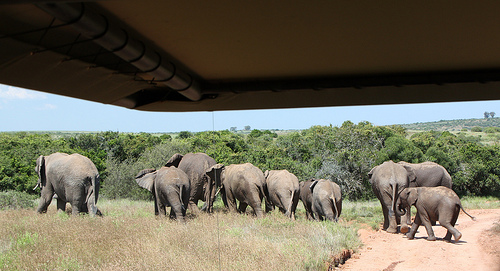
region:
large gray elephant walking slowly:
[19, 135, 101, 218]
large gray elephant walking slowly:
[140, 165, 197, 222]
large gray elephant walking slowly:
[166, 148, 210, 171]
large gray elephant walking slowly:
[207, 153, 264, 214]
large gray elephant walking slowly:
[267, 156, 302, 218]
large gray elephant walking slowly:
[298, 178, 347, 230]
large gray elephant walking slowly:
[389, 180, 469, 239]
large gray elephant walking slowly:
[345, 138, 471, 246]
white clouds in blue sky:
[97, 105, 119, 128]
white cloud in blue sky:
[13, 98, 53, 131]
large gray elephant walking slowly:
[20, 146, 100, 208]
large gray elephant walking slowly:
[132, 157, 187, 203]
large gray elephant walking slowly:
[166, 136, 211, 202]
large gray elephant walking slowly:
[200, 160, 245, 205]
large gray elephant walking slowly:
[260, 167, 306, 202]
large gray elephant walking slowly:
[300, 165, 345, 215]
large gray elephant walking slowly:
[375, 160, 455, 236]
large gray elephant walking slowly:
[385, 177, 475, 233]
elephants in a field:
[29, 116, 486, 253]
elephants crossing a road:
[348, 143, 497, 256]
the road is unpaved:
[343, 217, 496, 269]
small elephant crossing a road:
[385, 175, 475, 243]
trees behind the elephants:
[25, 112, 480, 243]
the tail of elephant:
[86, 171, 96, 212]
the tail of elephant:
[450, 200, 480, 225]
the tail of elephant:
[325, 192, 343, 218]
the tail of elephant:
[285, 182, 298, 212]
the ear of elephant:
[132, 163, 157, 192]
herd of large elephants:
[53, 137, 481, 250]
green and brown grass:
[77, 223, 315, 252]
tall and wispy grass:
[63, 216, 158, 270]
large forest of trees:
[41, 127, 496, 204]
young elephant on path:
[373, 163, 471, 240]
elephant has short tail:
[442, 192, 488, 237]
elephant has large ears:
[130, 166, 185, 216]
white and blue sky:
[3, 83, 67, 138]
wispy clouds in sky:
[1, 84, 68, 137]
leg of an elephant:
[37, 184, 51, 224]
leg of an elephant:
[65, 187, 85, 218]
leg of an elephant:
[169, 196, 191, 223]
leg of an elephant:
[250, 199, 274, 230]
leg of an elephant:
[388, 197, 408, 245]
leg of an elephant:
[411, 210, 420, 243]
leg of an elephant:
[420, 214, 437, 246]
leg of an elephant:
[440, 217, 464, 250]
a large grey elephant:
[368, 155, 413, 230]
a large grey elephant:
[306, 177, 348, 219]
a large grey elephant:
[266, 164, 298, 216]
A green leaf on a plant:
[214, 140, 220, 142]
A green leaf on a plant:
[23, 148, 25, 150]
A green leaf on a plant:
[35, 138, 39, 140]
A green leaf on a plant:
[90, 142, 95, 145]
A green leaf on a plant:
[105, 142, 109, 143]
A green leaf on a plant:
[129, 140, 134, 144]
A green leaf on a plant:
[440, 143, 448, 147]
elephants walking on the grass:
[18, 129, 340, 220]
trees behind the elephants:
[2, 122, 497, 191]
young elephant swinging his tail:
[393, 182, 470, 242]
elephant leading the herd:
[31, 152, 100, 217]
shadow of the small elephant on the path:
[408, 230, 465, 244]